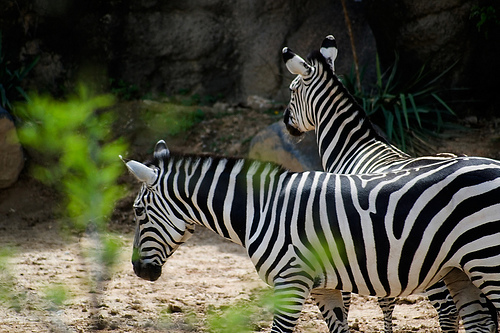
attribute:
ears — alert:
[268, 35, 344, 73]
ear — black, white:
[281, 45, 313, 80]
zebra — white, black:
[283, 34, 498, 330]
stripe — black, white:
[340, 174, 378, 298]